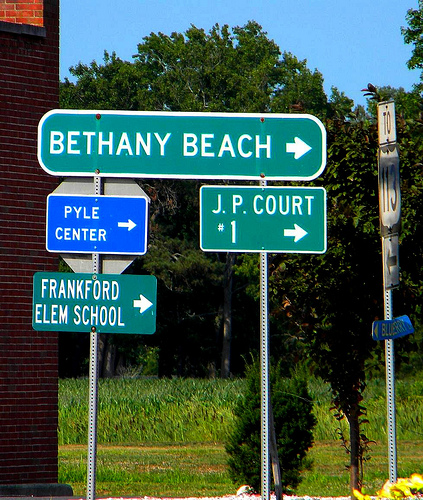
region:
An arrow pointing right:
[280, 133, 314, 162]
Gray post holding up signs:
[83, 174, 104, 497]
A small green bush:
[220, 348, 322, 494]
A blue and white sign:
[41, 189, 149, 258]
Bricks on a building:
[1, 0, 62, 482]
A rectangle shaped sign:
[195, 180, 330, 257]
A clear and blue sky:
[58, 0, 420, 111]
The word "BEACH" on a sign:
[178, 127, 277, 164]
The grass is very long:
[59, 369, 420, 446]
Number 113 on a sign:
[374, 149, 405, 222]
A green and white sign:
[32, 272, 157, 334]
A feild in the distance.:
[59, 377, 422, 445]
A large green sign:
[36, 109, 327, 180]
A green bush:
[222, 349, 318, 497]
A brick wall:
[0, 0, 59, 484]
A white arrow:
[282, 222, 307, 242]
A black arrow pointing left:
[384, 248, 397, 273]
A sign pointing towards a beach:
[36, 109, 326, 181]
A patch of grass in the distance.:
[55, 441, 422, 497]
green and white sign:
[37, 92, 342, 188]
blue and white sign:
[41, 172, 167, 240]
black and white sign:
[343, 85, 415, 305]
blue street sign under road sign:
[364, 299, 422, 351]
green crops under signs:
[99, 362, 244, 466]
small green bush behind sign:
[228, 340, 315, 494]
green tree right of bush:
[277, 257, 388, 498]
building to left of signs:
[4, 43, 61, 469]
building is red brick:
[8, 45, 55, 112]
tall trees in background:
[85, 45, 420, 373]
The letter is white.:
[46, 122, 66, 157]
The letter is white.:
[64, 126, 84, 156]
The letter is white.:
[83, 125, 98, 158]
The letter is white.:
[95, 129, 116, 158]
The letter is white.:
[113, 129, 135, 158]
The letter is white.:
[133, 125, 155, 158]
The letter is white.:
[151, 126, 177, 159]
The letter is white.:
[180, 125, 199, 163]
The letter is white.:
[197, 127, 216, 160]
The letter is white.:
[215, 127, 237, 161]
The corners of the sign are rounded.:
[28, 93, 333, 183]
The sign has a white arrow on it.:
[28, 101, 333, 183]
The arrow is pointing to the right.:
[30, 82, 336, 188]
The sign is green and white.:
[24, 100, 330, 182]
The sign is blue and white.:
[38, 186, 158, 263]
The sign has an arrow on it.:
[38, 188, 156, 260]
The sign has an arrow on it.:
[191, 183, 336, 262]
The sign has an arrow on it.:
[26, 266, 172, 337]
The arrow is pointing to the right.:
[40, 191, 157, 258]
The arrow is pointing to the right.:
[194, 179, 332, 269]